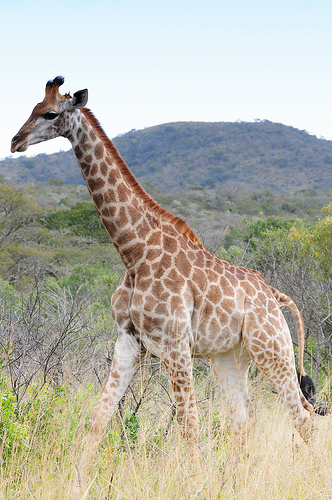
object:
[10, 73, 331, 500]
giraffe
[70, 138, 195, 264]
neck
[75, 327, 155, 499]
leg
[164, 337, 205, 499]
leg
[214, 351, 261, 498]
leg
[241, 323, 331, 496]
leg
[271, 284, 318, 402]
tail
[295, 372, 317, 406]
hair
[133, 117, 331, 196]
hill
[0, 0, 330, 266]
background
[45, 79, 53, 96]
horn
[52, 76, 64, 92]
horn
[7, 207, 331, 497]
ground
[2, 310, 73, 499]
greenery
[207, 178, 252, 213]
tree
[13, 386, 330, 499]
grass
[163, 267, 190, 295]
spot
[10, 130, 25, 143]
snout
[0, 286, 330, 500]
meadow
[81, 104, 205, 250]
mane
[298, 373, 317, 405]
tuft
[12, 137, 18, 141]
nostril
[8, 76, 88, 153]
head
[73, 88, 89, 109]
ear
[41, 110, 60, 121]
eye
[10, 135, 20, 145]
nose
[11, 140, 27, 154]
mouth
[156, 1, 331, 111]
sky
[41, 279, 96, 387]
branch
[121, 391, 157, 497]
branch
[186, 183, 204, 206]
tree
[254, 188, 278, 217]
tree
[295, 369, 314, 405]
tip